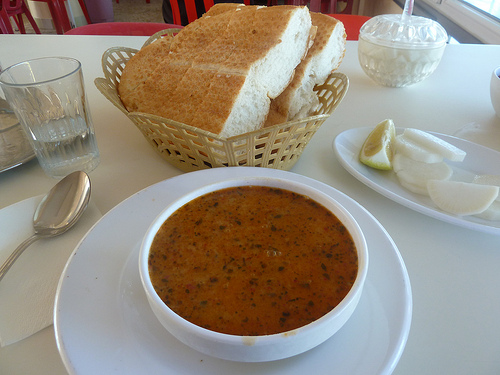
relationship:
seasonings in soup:
[222, 262, 249, 274] [174, 207, 336, 340]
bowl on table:
[136, 174, 371, 362] [2, 28, 498, 373]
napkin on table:
[0, 189, 105, 350] [2, 28, 498, 373]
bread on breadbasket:
[118, 3, 344, 136] [93, 27, 349, 179]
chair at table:
[53, 2, 233, 38] [2, 28, 498, 373]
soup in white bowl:
[153, 186, 353, 333] [133, 171, 370, 361]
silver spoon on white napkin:
[11, 160, 97, 247] [2, 200, 52, 330]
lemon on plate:
[362, 111, 396, 178] [333, 117, 464, 225]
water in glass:
[25, 118, 96, 174] [2, 50, 100, 173]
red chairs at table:
[1, 2, 426, 36] [2, 28, 498, 373]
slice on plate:
[353, 113, 403, 171] [336, 112, 486, 229]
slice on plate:
[419, 173, 499, 218] [336, 112, 486, 229]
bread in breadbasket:
[118, 3, 344, 136] [93, 27, 349, 179]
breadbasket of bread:
[93, 27, 349, 179] [118, 3, 344, 136]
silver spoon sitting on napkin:
[0, 170, 91, 281] [3, 221, 84, 342]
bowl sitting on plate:
[133, 175, 382, 369] [74, 262, 144, 364]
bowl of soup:
[133, 175, 382, 369] [171, 197, 341, 309]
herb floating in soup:
[271, 223, 278, 232] [153, 186, 353, 333]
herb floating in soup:
[209, 271, 218, 283] [153, 186, 353, 333]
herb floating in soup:
[250, 275, 257, 283] [153, 186, 353, 333]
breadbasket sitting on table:
[78, 42, 432, 194] [2, 28, 498, 373]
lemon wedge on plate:
[357, 112, 396, 186] [347, 110, 500, 225]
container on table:
[351, 0, 458, 94] [403, 223, 487, 335]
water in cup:
[31, 115, 95, 166] [4, 56, 98, 171]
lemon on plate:
[356, 117, 396, 169] [53, 164, 415, 373]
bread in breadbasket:
[115, 1, 347, 171] [93, 27, 349, 179]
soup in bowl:
[153, 186, 353, 333] [134, 172, 367, 363]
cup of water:
[0, 56, 102, 177] [23, 134, 90, 166]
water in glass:
[34, 114, 87, 168] [5, 58, 112, 164]